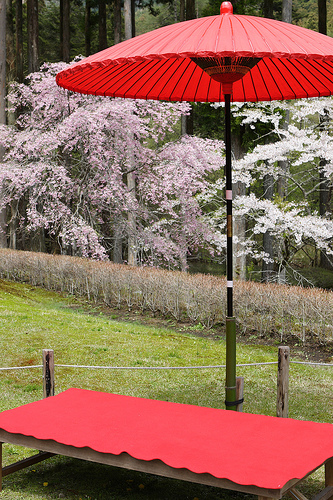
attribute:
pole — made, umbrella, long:
[216, 84, 237, 411]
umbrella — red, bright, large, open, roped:
[39, 0, 332, 105]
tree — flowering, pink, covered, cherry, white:
[1, 53, 235, 271]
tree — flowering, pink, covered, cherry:
[228, 94, 333, 285]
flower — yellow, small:
[41, 477, 52, 488]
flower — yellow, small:
[136, 481, 148, 493]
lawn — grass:
[1, 273, 332, 498]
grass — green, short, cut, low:
[0, 274, 330, 495]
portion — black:
[223, 95, 238, 318]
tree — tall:
[59, 0, 85, 60]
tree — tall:
[123, 1, 138, 38]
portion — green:
[223, 313, 241, 408]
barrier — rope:
[2, 339, 332, 473]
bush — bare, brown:
[280, 283, 313, 344]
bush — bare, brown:
[191, 271, 222, 331]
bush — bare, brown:
[120, 265, 147, 314]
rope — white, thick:
[1, 359, 331, 373]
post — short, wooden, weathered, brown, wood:
[276, 344, 294, 419]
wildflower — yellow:
[40, 479, 56, 491]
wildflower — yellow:
[135, 479, 147, 491]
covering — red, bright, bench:
[0, 385, 333, 493]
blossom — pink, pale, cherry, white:
[258, 226, 270, 236]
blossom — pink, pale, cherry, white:
[289, 161, 306, 168]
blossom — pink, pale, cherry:
[247, 123, 257, 131]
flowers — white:
[2, 49, 227, 244]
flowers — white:
[215, 94, 333, 270]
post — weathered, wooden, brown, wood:
[41, 350, 59, 394]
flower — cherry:
[256, 172, 268, 182]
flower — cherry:
[321, 166, 332, 178]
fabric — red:
[54, 16, 332, 102]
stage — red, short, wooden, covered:
[4, 381, 333, 498]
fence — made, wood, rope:
[3, 344, 332, 473]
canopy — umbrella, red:
[56, 1, 332, 101]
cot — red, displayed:
[3, 384, 332, 492]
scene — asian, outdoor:
[3, 0, 332, 495]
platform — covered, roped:
[4, 382, 333, 499]